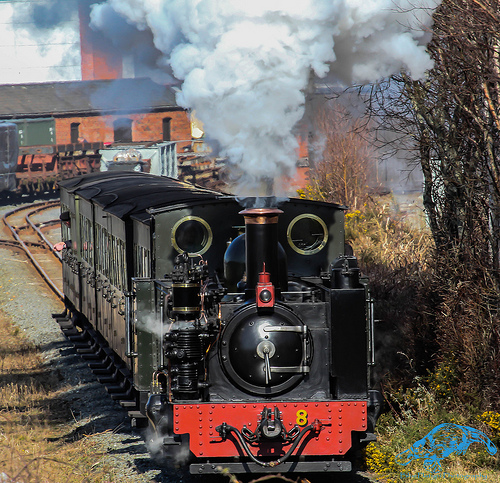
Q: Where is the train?
A: The train tracks.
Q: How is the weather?
A: Sunny.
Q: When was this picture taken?
A: Daytime.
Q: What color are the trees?
A: Green.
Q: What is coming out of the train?
A: Steam.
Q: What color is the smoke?
A: White.